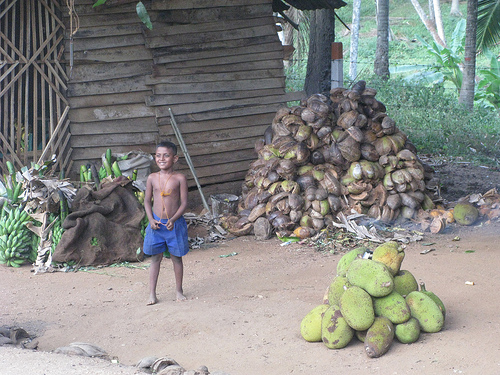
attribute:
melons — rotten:
[239, 81, 465, 254]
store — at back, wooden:
[2, 2, 294, 219]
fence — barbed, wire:
[267, 2, 499, 210]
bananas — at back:
[0, 153, 41, 271]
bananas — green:
[1, 179, 40, 272]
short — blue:
[140, 213, 190, 257]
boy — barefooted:
[144, 135, 186, 305]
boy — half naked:
[147, 142, 189, 306]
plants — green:
[387, 79, 499, 152]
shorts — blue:
[145, 204, 197, 264]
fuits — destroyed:
[230, 71, 449, 227]